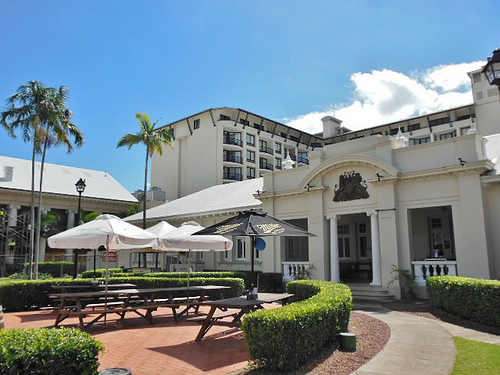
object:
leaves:
[281, 313, 314, 343]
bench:
[58, 304, 181, 326]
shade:
[14, 270, 294, 371]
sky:
[1, 0, 500, 196]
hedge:
[242, 278, 352, 373]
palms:
[0, 77, 84, 157]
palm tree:
[0, 79, 83, 279]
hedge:
[426, 274, 499, 337]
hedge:
[0, 322, 107, 374]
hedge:
[0, 279, 100, 309]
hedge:
[98, 276, 245, 301]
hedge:
[17, 260, 78, 279]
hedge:
[82, 267, 123, 278]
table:
[193, 288, 295, 342]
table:
[48, 287, 160, 326]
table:
[153, 284, 233, 313]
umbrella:
[46, 209, 149, 292]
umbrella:
[142, 220, 182, 299]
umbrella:
[157, 216, 230, 288]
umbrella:
[189, 207, 320, 295]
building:
[143, 52, 499, 304]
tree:
[115, 110, 176, 267]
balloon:
[253, 237, 267, 250]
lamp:
[74, 179, 86, 194]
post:
[72, 193, 83, 278]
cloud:
[269, 60, 489, 136]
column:
[366, 210, 382, 286]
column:
[326, 216, 341, 284]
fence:
[282, 261, 311, 281]